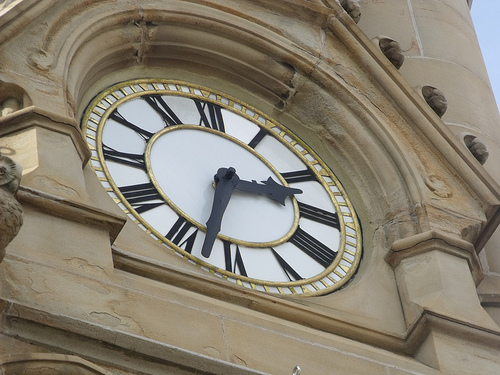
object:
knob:
[421, 84, 447, 117]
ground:
[456, 130, 491, 171]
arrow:
[260, 175, 303, 206]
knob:
[463, 134, 489, 166]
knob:
[378, 37, 404, 70]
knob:
[339, 0, 362, 25]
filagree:
[82, 77, 364, 298]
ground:
[392, 152, 423, 210]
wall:
[3, 2, 498, 372]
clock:
[80, 78, 361, 299]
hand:
[218, 167, 305, 206]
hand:
[201, 167, 240, 258]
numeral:
[101, 143, 147, 174]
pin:
[213, 167, 240, 192]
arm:
[213, 176, 304, 206]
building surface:
[0, 0, 500, 375]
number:
[117, 180, 166, 215]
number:
[287, 224, 339, 268]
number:
[296, 200, 341, 232]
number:
[140, 92, 184, 128]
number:
[165, 213, 200, 255]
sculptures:
[266, 45, 374, 114]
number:
[218, 238, 249, 278]